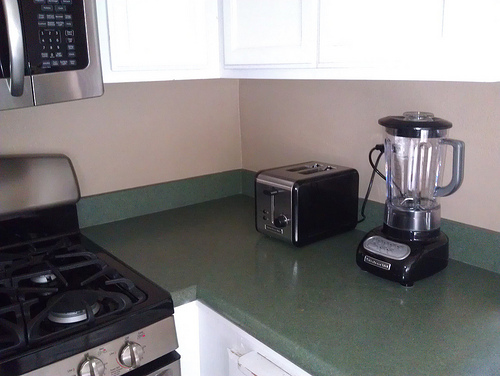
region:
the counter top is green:
[79, 166, 498, 373]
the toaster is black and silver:
[252, 159, 359, 246]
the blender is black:
[353, 109, 466, 286]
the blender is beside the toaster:
[251, 109, 468, 289]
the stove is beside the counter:
[3, 134, 498, 372]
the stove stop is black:
[0, 154, 181, 374]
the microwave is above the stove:
[2, 2, 184, 374]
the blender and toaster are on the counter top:
[78, 110, 498, 372]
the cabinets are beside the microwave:
[0, 0, 496, 112]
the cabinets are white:
[95, 2, 497, 87]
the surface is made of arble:
[306, 267, 402, 373]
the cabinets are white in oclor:
[218, 345, 258, 372]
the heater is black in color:
[255, 162, 362, 240]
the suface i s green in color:
[331, 277, 432, 374]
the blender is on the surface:
[381, 138, 456, 265]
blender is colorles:
[375, 150, 463, 225]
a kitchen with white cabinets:
[3, 7, 456, 357]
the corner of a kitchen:
[202, 90, 267, 162]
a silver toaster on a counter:
[246, 160, 336, 256]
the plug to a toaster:
[348, 142, 389, 216]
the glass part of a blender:
[374, 102, 469, 222]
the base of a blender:
[360, 226, 452, 288]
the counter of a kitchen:
[167, 215, 259, 295]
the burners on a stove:
[1, 238, 138, 332]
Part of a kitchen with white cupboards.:
[1, 0, 499, 375]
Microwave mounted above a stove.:
[0, 0, 102, 115]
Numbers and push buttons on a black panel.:
[28, 3, 85, 70]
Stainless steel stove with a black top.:
[0, 153, 183, 375]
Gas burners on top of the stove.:
[27, 258, 103, 324]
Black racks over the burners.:
[5, 246, 140, 340]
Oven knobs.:
[76, 338, 146, 374]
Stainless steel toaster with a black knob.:
[257, 161, 361, 248]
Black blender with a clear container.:
[354, 110, 465, 282]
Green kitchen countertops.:
[79, 166, 499, 374]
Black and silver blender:
[355, 109, 463, 289]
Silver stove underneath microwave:
[1, 151, 181, 374]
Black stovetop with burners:
[1, 229, 176, 374]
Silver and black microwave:
[0, 4, 105, 112]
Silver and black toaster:
[255, 157, 360, 249]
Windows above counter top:
[95, 3, 499, 83]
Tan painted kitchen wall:
[2, 76, 499, 274]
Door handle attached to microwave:
[2, 5, 25, 100]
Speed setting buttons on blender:
[360, 233, 411, 260]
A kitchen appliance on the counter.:
[226, 126, 363, 248]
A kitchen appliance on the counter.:
[376, 104, 456, 297]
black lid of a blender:
[377, 111, 452, 139]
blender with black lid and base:
[355, 111, 463, 286]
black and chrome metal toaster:
[253, 159, 360, 246]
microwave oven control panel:
[32, 1, 78, 68]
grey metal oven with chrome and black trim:
[1, 154, 183, 373]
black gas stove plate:
[14, 260, 145, 338]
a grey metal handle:
[1, 1, 24, 96]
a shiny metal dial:
[118, 340, 145, 368]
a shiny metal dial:
[78, 352, 105, 374]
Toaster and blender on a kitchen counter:
[249, 106, 466, 289]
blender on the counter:
[356, 107, 466, 289]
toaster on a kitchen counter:
[249, 155, 359, 249]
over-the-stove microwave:
[1, 1, 106, 118]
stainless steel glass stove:
[1, 150, 182, 373]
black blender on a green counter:
[353, 105, 470, 294]